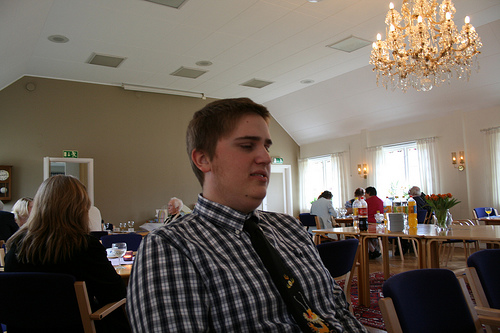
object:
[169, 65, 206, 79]
air vent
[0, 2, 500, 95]
ceiling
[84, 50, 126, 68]
air vent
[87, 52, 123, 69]
vent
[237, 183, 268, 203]
chin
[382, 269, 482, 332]
chairs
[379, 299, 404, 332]
arms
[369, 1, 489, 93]
chandelier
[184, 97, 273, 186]
hair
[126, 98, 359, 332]
guy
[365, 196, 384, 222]
shirt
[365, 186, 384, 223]
person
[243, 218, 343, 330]
tie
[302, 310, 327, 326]
design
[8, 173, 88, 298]
woman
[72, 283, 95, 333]
chair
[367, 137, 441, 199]
curtains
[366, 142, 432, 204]
window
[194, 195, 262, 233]
collar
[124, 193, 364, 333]
shirt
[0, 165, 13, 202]
clock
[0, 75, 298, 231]
wall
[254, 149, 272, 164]
nose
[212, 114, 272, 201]
face